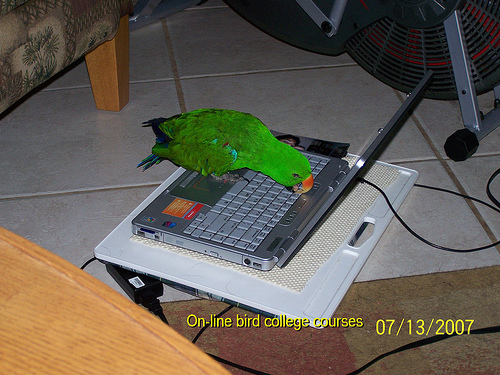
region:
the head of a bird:
[272, 145, 321, 197]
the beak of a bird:
[283, 170, 318, 199]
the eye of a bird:
[287, 168, 304, 183]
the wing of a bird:
[146, 132, 241, 179]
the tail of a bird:
[130, 150, 167, 177]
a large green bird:
[124, 102, 321, 198]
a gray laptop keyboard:
[178, 138, 335, 254]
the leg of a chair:
[82, 12, 142, 119]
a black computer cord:
[361, 172, 498, 268]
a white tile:
[0, 71, 188, 201]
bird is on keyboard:
[145, 96, 330, 223]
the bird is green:
[138, 92, 364, 214]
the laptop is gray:
[141, 79, 438, 278]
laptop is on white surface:
[91, 90, 452, 327]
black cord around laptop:
[85, 262, 499, 367]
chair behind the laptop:
[3, 6, 178, 101]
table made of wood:
[1, 210, 203, 372]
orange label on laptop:
[159, 187, 202, 226]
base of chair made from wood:
[81, 30, 142, 122]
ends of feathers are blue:
[145, 110, 172, 178]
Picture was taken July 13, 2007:
[177, 304, 484, 344]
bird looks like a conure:
[128, 104, 321, 196]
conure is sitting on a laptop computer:
[120, 72, 437, 277]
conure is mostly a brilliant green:
[131, 102, 318, 197]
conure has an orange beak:
[131, 104, 323, 197]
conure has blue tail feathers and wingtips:
[128, 105, 323, 200]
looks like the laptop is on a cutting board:
[85, 111, 424, 344]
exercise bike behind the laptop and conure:
[208, 0, 498, 160]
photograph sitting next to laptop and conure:
[196, 110, 363, 163]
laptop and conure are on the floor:
[45, 55, 475, 283]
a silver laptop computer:
[120, 73, 428, 270]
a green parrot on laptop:
[145, 105, 311, 204]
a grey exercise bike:
[226, 0, 498, 162]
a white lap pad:
[94, 116, 416, 329]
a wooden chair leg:
[84, 19, 134, 116]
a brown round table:
[1, 226, 224, 373]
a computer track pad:
[183, 165, 228, 195]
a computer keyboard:
[181, 140, 325, 255]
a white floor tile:
[187, 55, 433, 184]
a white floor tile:
[0, 68, 199, 207]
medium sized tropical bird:
[133, 101, 328, 201]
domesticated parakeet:
[132, 100, 332, 202]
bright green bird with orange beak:
[130, 99, 333, 201]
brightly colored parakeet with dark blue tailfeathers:
[113, 95, 324, 197]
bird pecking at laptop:
[123, 97, 325, 196]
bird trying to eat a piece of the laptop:
[126, 107, 333, 199]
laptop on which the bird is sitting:
[126, 68, 436, 274]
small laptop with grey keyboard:
[130, 50, 438, 275]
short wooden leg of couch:
[73, 15, 145, 131]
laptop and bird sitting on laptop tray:
[97, 71, 437, 337]